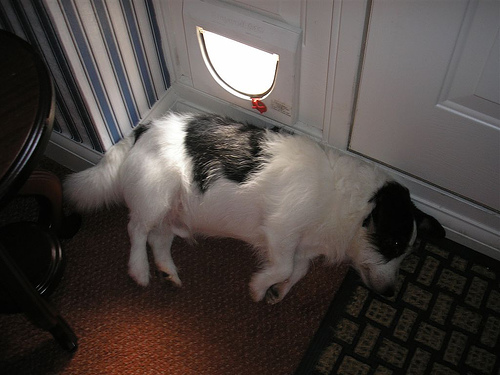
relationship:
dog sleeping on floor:
[60, 111, 445, 303] [1, 158, 499, 373]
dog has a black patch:
[60, 111, 445, 303] [186, 117, 264, 195]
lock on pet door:
[251, 100, 267, 114] [172, 3, 303, 128]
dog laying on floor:
[60, 111, 445, 303] [1, 158, 499, 373]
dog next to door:
[60, 111, 445, 303] [345, 1, 499, 212]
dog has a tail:
[60, 111, 445, 303] [62, 131, 132, 211]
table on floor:
[2, 27, 81, 353] [1, 158, 499, 373]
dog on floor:
[60, 111, 445, 303] [1, 158, 499, 373]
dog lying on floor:
[60, 111, 445, 303] [1, 158, 499, 373]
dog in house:
[60, 111, 445, 303] [3, 1, 496, 375]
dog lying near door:
[60, 111, 445, 303] [345, 1, 499, 212]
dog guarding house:
[60, 111, 445, 303] [3, 1, 496, 375]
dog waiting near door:
[60, 111, 445, 303] [345, 1, 499, 212]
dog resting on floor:
[60, 111, 445, 303] [1, 158, 499, 373]